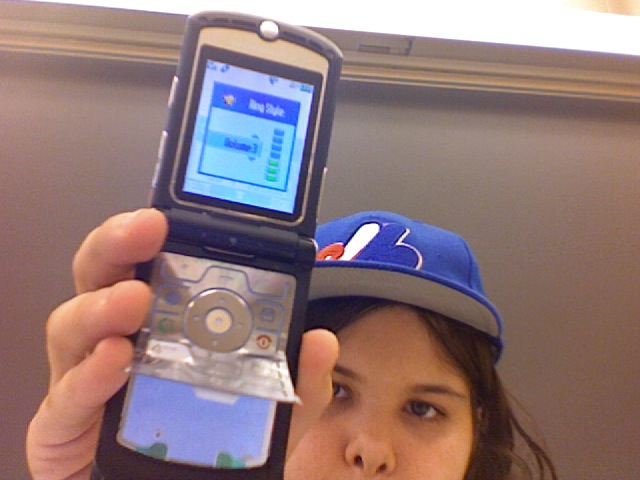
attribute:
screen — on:
[183, 44, 315, 217]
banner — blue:
[215, 83, 305, 127]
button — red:
[249, 330, 279, 353]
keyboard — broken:
[124, 251, 303, 408]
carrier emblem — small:
[256, 16, 280, 43]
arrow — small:
[214, 292, 232, 311]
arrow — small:
[231, 319, 248, 334]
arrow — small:
[207, 337, 223, 355]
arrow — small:
[189, 316, 202, 326]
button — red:
[256, 333, 275, 353]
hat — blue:
[304, 207, 502, 366]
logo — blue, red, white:
[313, 217, 422, 270]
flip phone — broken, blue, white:
[93, 12, 343, 477]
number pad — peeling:
[119, 250, 301, 409]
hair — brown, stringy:
[299, 294, 558, 477]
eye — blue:
[401, 397, 444, 417]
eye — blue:
[328, 378, 351, 400]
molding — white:
[5, 5, 639, 96]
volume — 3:
[210, 131, 277, 158]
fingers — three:
[26, 193, 180, 468]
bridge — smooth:
[329, 385, 411, 472]